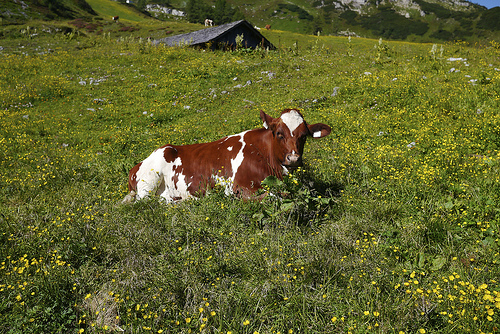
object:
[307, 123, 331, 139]
ear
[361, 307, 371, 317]
flower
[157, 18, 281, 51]
roof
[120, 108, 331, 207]
cow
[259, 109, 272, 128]
ear